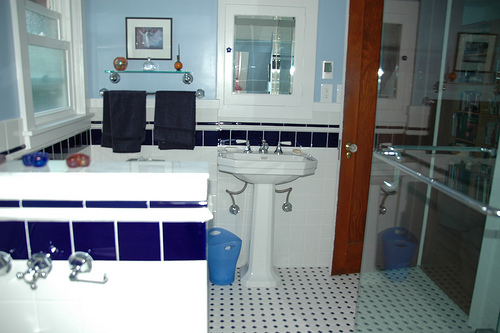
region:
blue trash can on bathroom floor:
[211, 217, 245, 295]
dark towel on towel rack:
[99, 83, 151, 159]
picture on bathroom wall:
[116, 11, 182, 67]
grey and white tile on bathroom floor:
[293, 297, 339, 325]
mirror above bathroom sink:
[218, 3, 310, 113]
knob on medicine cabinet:
[221, 42, 236, 61]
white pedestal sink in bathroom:
[210, 132, 325, 295]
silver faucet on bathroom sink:
[254, 132, 274, 161]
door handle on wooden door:
[338, 133, 361, 167]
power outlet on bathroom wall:
[315, 79, 336, 112]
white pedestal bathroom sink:
[220, 150, 310, 288]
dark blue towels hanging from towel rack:
[96, 88, 213, 153]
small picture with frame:
[120, 16, 174, 61]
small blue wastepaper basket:
[203, 222, 245, 285]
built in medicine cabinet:
[212, 3, 320, 111]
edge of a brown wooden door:
[329, 0, 379, 280]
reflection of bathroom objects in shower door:
[343, 3, 497, 325]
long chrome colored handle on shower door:
[373, 142, 498, 234]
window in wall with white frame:
[23, 8, 71, 140]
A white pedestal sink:
[217, 137, 318, 288]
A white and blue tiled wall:
[0, 171, 213, 332]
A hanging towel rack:
[99, 87, 206, 101]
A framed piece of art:
[124, 14, 175, 61]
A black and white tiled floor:
[209, 266, 476, 332]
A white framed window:
[8, 1, 95, 147]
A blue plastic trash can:
[206, 226, 243, 288]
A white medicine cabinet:
[214, 3, 321, 120]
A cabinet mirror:
[233, 15, 296, 100]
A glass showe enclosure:
[350, 1, 499, 331]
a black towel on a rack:
[149, 87, 199, 156]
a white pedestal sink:
[214, 149, 322, 289]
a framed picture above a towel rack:
[119, 13, 177, 66]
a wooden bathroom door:
[328, 0, 382, 276]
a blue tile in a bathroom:
[116, 219, 162, 267]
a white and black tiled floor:
[208, 262, 356, 331]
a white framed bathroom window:
[21, 0, 75, 138]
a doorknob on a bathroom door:
[347, 141, 359, 155]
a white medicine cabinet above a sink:
[216, 0, 319, 112]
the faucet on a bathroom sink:
[256, 136, 270, 155]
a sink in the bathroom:
[211, 131, 311, 291]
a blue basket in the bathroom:
[205, 222, 240, 283]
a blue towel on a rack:
[100, 84, 152, 155]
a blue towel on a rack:
[150, 87, 197, 151]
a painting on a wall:
[121, 12, 173, 59]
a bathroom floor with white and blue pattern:
[203, 257, 496, 328]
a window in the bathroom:
[15, 0, 82, 129]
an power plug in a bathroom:
[318, 84, 334, 103]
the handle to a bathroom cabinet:
[226, 43, 231, 55]